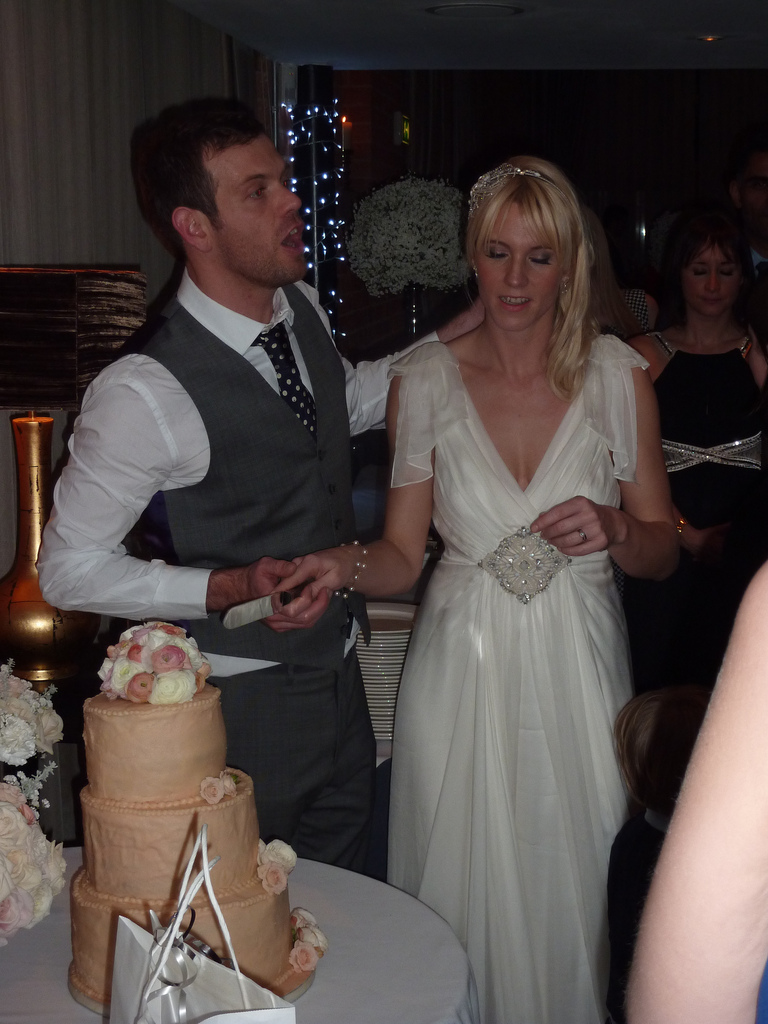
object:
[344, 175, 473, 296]
bush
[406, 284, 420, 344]
vase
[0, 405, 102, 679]
lamp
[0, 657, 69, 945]
floral arrangement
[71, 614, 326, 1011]
cake